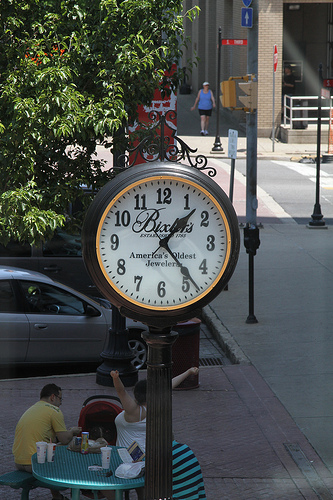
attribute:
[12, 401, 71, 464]
shirt — yellow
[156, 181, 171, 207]
number — black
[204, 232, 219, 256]
number — black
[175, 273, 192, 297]
number — black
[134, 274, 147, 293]
number — black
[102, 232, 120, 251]
number — black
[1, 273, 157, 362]
car — silver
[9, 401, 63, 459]
shirt — yellow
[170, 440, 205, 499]
shirt — striped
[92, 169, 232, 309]
circle — gold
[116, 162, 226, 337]
clock — metal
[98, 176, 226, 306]
face — white